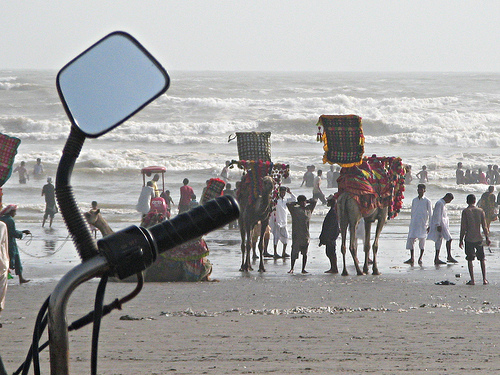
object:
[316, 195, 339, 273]
person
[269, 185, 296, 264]
person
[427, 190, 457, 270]
person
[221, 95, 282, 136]
waves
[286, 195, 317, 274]
man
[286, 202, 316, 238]
brown tunic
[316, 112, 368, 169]
seat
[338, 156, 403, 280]
camel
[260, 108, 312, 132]
wave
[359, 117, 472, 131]
wave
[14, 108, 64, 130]
wave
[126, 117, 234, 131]
wave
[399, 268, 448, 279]
shore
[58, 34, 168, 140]
glass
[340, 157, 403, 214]
saddling cloth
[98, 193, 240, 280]
grip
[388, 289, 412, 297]
sand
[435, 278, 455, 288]
trash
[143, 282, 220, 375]
shore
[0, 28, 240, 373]
motorbike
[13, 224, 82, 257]
tether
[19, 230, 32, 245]
hand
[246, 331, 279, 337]
sand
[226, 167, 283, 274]
camel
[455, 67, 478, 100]
water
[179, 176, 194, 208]
person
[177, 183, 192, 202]
red shirt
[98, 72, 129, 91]
sky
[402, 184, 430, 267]
man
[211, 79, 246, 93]
water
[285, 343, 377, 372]
beach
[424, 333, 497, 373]
beach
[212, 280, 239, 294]
sand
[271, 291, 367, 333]
beach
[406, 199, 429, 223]
tunic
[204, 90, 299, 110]
foam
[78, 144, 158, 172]
wave